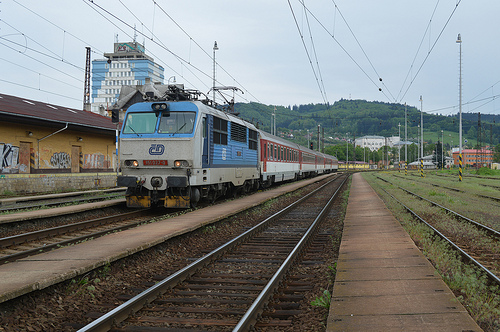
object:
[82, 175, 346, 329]
train tracks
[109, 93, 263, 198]
train engine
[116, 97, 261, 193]
front car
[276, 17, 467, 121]
wires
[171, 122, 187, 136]
wiper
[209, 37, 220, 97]
light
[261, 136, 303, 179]
train car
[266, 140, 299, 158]
windows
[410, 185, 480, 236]
grass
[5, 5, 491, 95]
lines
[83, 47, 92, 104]
pole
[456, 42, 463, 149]
pole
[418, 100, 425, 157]
pole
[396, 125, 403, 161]
pole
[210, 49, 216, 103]
pole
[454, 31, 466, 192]
post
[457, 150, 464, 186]
color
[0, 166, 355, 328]
tracks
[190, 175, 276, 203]
wheels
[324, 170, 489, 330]
concrete walkway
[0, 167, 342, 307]
concrete walkway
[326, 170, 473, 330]
pathway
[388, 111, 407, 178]
pole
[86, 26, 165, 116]
building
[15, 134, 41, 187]
door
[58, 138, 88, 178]
door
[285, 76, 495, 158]
hill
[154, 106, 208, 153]
floor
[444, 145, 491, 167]
building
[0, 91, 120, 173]
building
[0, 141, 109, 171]
graffiti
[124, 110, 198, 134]
windshield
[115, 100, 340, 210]
train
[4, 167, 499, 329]
railroad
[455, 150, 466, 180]
pole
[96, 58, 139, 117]
design